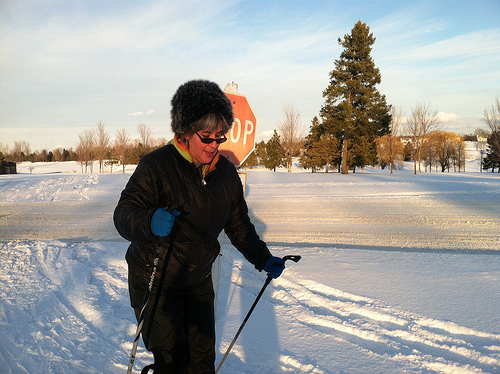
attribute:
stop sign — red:
[208, 93, 258, 168]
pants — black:
[122, 257, 217, 372]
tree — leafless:
[403, 104, 445, 174]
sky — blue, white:
[7, 6, 479, 143]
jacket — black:
[143, 142, 273, 289]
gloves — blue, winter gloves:
[142, 190, 179, 240]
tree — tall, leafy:
[299, 21, 396, 170]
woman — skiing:
[107, 79, 486, 371]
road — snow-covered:
[2, 199, 499, 246]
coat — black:
[111, 144, 271, 311]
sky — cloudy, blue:
[3, 0, 498, 170]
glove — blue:
[148, 203, 179, 235]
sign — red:
[226, 89, 261, 166]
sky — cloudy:
[17, 30, 170, 123]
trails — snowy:
[3, 240, 499, 370]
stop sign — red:
[219, 87, 261, 170]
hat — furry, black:
[163, 73, 238, 123]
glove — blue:
[152, 203, 184, 241]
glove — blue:
[263, 254, 287, 279]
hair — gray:
[171, 79, 234, 144]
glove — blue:
[150, 210, 182, 233]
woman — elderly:
[115, 80, 284, 370]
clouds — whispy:
[11, 4, 485, 136]